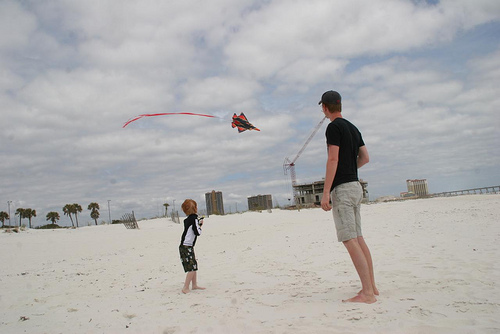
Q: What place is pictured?
A: It is a beach.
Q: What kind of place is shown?
A: It is a beach.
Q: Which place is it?
A: It is a beach.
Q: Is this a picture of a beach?
A: Yes, it is showing a beach.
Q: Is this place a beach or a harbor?
A: It is a beach.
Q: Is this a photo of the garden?
A: No, the picture is showing the beach.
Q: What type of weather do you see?
A: It is cloudy.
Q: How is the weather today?
A: It is cloudy.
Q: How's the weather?
A: It is cloudy.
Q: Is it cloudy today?
A: Yes, it is cloudy.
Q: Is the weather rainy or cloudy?
A: It is cloudy.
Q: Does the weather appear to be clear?
A: No, it is cloudy.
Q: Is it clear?
A: No, it is cloudy.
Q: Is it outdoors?
A: Yes, it is outdoors.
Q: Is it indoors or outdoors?
A: It is outdoors.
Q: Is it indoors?
A: No, it is outdoors.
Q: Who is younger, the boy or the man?
A: The boy is younger than the man.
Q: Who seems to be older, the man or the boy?
A: The man is older than the boy.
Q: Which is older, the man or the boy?
A: The man is older than the boy.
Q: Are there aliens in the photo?
A: No, there are no aliens.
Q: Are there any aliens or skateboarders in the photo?
A: No, there are no aliens or skateboarders.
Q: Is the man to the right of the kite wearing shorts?
A: Yes, the man is wearing shorts.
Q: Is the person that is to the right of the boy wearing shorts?
A: Yes, the man is wearing shorts.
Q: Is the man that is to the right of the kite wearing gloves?
A: No, the man is wearing shorts.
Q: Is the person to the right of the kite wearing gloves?
A: No, the man is wearing shorts.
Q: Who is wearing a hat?
A: The man is wearing a hat.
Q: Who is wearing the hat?
A: The man is wearing a hat.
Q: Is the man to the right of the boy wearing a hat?
A: Yes, the man is wearing a hat.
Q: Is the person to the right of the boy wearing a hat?
A: Yes, the man is wearing a hat.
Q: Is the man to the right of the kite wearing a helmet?
A: No, the man is wearing a hat.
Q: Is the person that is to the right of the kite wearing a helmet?
A: No, the man is wearing a hat.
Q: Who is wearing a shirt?
A: The man is wearing a shirt.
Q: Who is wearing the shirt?
A: The man is wearing a shirt.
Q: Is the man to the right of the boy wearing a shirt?
A: Yes, the man is wearing a shirt.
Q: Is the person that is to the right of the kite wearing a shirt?
A: Yes, the man is wearing a shirt.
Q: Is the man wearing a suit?
A: No, the man is wearing a shirt.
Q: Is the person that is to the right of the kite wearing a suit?
A: No, the man is wearing a shirt.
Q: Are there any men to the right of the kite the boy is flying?
A: Yes, there is a man to the right of the kite.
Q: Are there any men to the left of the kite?
A: No, the man is to the right of the kite.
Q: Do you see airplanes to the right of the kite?
A: No, there is a man to the right of the kite.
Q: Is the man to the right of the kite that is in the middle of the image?
A: Yes, the man is to the right of the kite.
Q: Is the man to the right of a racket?
A: No, the man is to the right of the kite.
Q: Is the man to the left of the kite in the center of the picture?
A: No, the man is to the right of the kite.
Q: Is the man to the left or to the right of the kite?
A: The man is to the right of the kite.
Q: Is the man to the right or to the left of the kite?
A: The man is to the right of the kite.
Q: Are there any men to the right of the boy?
A: Yes, there is a man to the right of the boy.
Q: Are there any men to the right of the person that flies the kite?
A: Yes, there is a man to the right of the boy.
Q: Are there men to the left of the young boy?
A: No, the man is to the right of the boy.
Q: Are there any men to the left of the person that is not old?
A: No, the man is to the right of the boy.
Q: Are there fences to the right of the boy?
A: No, there is a man to the right of the boy.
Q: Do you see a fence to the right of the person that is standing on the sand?
A: No, there is a man to the right of the boy.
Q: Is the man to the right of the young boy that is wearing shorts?
A: Yes, the man is to the right of the boy.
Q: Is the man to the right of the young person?
A: Yes, the man is to the right of the boy.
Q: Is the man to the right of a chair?
A: No, the man is to the right of the boy.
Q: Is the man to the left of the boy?
A: No, the man is to the right of the boy.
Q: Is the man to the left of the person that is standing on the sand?
A: No, the man is to the right of the boy.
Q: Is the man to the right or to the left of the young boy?
A: The man is to the right of the boy.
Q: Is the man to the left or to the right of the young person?
A: The man is to the right of the boy.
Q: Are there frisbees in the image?
A: No, there are no frisbees.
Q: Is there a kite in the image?
A: Yes, there is a kite.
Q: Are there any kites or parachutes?
A: Yes, there is a kite.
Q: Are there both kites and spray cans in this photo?
A: No, there is a kite but no spray cans.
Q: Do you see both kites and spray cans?
A: No, there is a kite but no spray cans.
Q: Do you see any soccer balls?
A: No, there are no soccer balls.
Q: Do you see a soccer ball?
A: No, there are no soccer balls.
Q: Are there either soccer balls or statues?
A: No, there are no soccer balls or statues.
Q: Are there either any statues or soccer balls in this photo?
A: No, there are no soccer balls or statues.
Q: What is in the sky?
A: The kite is in the sky.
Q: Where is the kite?
A: The kite is in the sky.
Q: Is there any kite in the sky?
A: Yes, there is a kite in the sky.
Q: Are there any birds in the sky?
A: No, there is a kite in the sky.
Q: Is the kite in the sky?
A: Yes, the kite is in the sky.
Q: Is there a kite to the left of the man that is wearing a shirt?
A: Yes, there is a kite to the left of the man.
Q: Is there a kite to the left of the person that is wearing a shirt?
A: Yes, there is a kite to the left of the man.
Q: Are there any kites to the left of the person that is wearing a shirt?
A: Yes, there is a kite to the left of the man.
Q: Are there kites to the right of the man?
A: No, the kite is to the left of the man.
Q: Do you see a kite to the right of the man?
A: No, the kite is to the left of the man.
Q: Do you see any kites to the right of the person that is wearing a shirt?
A: No, the kite is to the left of the man.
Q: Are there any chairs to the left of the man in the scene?
A: No, there is a kite to the left of the man.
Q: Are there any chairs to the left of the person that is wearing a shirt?
A: No, there is a kite to the left of the man.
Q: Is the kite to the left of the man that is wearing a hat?
A: Yes, the kite is to the left of the man.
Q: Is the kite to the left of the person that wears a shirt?
A: Yes, the kite is to the left of the man.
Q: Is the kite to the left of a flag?
A: No, the kite is to the left of the man.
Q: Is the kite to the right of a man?
A: No, the kite is to the left of a man.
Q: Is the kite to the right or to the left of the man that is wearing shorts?
A: The kite is to the left of the man.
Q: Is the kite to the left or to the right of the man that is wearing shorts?
A: The kite is to the left of the man.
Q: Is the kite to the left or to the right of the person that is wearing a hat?
A: The kite is to the left of the man.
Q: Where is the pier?
A: The pier is on the beach.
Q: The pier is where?
A: The pier is on the beach.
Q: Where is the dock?
A: The pier is on the beach.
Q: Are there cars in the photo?
A: No, there are no cars.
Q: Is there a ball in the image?
A: No, there are no balls.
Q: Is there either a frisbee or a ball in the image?
A: No, there are no balls or frisbees.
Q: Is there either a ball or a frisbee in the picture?
A: No, there are no balls or frisbees.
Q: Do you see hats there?
A: Yes, there is a hat.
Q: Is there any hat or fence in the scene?
A: Yes, there is a hat.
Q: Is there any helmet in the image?
A: No, there are no helmets.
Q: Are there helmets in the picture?
A: No, there are no helmets.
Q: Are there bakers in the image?
A: No, there are no bakers.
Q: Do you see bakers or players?
A: No, there are no bakers or players.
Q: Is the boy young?
A: Yes, the boy is young.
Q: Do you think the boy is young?
A: Yes, the boy is young.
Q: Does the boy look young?
A: Yes, the boy is young.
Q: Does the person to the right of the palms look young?
A: Yes, the boy is young.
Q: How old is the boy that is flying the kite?
A: The boy is young.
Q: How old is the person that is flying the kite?
A: The boy is young.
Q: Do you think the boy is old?
A: No, the boy is young.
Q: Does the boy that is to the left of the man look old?
A: No, the boy is young.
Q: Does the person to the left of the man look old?
A: No, the boy is young.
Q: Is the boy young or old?
A: The boy is young.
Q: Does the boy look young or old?
A: The boy is young.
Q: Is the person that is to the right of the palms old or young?
A: The boy is young.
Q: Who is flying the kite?
A: The boy is flying the kite.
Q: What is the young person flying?
A: The boy is flying the kite.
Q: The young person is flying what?
A: The boy is flying the kite.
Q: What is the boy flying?
A: The boy is flying the kite.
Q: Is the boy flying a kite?
A: Yes, the boy is flying a kite.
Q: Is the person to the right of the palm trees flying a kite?
A: Yes, the boy is flying a kite.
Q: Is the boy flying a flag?
A: No, the boy is flying a kite.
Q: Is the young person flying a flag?
A: No, the boy is flying a kite.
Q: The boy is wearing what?
A: The boy is wearing shorts.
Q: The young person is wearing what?
A: The boy is wearing shorts.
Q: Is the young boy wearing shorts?
A: Yes, the boy is wearing shorts.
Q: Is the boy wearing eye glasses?
A: No, the boy is wearing shorts.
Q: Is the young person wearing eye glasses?
A: No, the boy is wearing shorts.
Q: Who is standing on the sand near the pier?
A: The boy is standing on the sand.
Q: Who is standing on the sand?
A: The boy is standing on the sand.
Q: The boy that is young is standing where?
A: The boy is standing on the sand.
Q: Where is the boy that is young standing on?
A: The boy is standing on the sand.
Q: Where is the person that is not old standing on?
A: The boy is standing on the sand.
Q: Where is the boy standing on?
A: The boy is standing on the sand.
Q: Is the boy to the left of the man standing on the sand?
A: Yes, the boy is standing on the sand.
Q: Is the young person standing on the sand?
A: Yes, the boy is standing on the sand.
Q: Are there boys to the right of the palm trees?
A: Yes, there is a boy to the right of the palm trees.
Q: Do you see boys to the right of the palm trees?
A: Yes, there is a boy to the right of the palm trees.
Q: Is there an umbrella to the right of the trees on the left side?
A: No, there is a boy to the right of the palms.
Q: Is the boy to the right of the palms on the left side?
A: Yes, the boy is to the right of the palm trees.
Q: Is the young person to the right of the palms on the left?
A: Yes, the boy is to the right of the palm trees.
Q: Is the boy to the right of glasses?
A: No, the boy is to the right of the palm trees.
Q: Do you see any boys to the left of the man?
A: Yes, there is a boy to the left of the man.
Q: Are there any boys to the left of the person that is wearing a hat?
A: Yes, there is a boy to the left of the man.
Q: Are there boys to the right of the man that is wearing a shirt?
A: No, the boy is to the left of the man.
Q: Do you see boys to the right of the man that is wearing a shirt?
A: No, the boy is to the left of the man.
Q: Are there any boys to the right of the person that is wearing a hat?
A: No, the boy is to the left of the man.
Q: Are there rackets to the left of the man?
A: No, there is a boy to the left of the man.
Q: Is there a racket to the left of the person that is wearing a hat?
A: No, there is a boy to the left of the man.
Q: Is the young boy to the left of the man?
A: Yes, the boy is to the left of the man.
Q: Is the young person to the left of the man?
A: Yes, the boy is to the left of the man.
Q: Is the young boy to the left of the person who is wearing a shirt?
A: Yes, the boy is to the left of the man.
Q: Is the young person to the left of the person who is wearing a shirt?
A: Yes, the boy is to the left of the man.